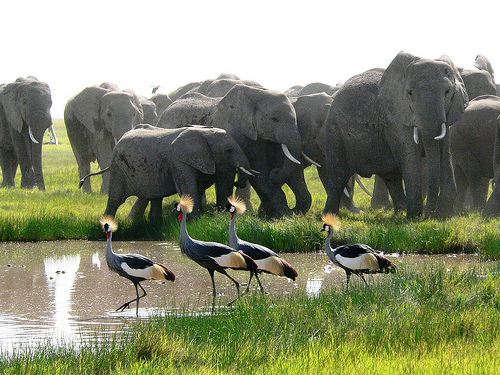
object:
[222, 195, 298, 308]
bird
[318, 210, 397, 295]
bird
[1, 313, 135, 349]
ripples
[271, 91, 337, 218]
elephant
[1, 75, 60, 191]
elephant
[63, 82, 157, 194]
elephant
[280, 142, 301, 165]
tusk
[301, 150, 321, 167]
tusk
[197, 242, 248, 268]
wing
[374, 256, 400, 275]
tail feathers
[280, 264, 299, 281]
tail feathers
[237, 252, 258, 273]
tail feathers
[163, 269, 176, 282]
tail feathers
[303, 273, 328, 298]
reflection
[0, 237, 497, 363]
water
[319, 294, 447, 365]
grass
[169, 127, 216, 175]
ear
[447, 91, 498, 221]
elephant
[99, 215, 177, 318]
bird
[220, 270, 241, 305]
legs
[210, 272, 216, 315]
legs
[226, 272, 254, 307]
legs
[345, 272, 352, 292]
legs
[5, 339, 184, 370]
grass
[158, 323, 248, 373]
grass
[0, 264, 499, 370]
ground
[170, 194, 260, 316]
bird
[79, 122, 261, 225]
elephant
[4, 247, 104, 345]
pond water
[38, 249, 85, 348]
reflection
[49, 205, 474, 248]
grass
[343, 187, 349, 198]
tusks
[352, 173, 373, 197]
tusks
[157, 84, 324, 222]
elephant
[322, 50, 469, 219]
elephant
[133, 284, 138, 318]
leg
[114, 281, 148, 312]
leg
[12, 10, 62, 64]
air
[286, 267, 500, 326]
grass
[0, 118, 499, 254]
ground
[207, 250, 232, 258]
edge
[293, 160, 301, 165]
tip